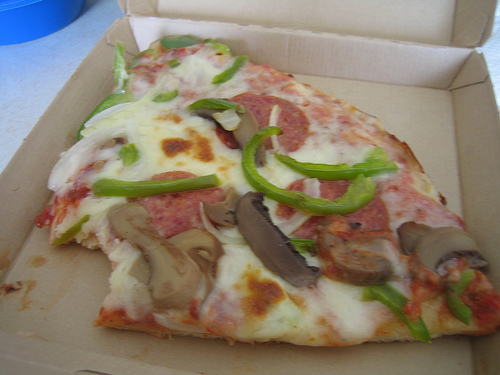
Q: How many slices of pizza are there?
A: 1.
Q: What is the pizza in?
A: Cardboard box.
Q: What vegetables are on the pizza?
A: Mushroom, bell pepper, onion.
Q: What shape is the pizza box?
A: Square.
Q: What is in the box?
A: Pizza.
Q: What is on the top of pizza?
A: Cheese.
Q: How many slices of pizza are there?
A: One.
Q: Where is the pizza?
A: In the box.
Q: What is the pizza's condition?
A: It has bite on it.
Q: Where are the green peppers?
A: On the top of the pizza.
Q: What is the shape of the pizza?
A: Triangular.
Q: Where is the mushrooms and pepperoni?
A: On top of the pizza.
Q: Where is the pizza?
A: Inside the box.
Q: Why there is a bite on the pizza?
A: Someone bite into it.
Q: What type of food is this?
A: Pizza.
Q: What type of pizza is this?
A: Supreme.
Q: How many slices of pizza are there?
A: One.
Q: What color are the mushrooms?
A: Brown.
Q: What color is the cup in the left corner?
A: Blue.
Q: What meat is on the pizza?
A: Pepperoni.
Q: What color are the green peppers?
A: Green.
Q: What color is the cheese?
A: White.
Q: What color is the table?
A: White.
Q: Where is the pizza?
A: In the box.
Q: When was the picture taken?
A: Daytime.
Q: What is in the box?
A: Pizza.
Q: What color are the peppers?
A: Green.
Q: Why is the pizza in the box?
A: Waiting to be eaten.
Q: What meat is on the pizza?
A: Pepperoni.